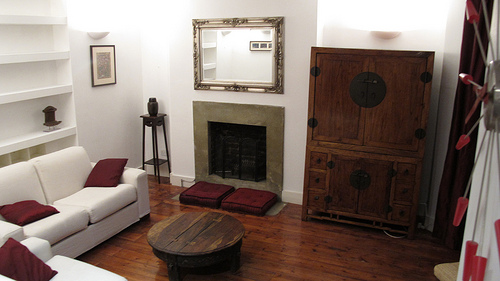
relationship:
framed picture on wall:
[89, 44, 117, 86] [125, 35, 167, 86]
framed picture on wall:
[84, 39, 129, 85] [125, 35, 167, 86]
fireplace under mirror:
[167, 102, 307, 207] [182, 7, 300, 102]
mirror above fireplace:
[191, 16, 285, 94] [190, 99, 288, 197]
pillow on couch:
[85, 155, 129, 186] [0, 142, 150, 258]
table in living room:
[146, 209, 248, 278] [0, 0, 500, 281]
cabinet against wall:
[298, 45, 435, 242] [135, 0, 466, 230]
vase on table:
[147, 97, 159, 117] [140, 112, 170, 182]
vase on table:
[142, 93, 167, 120] [134, 111, 180, 186]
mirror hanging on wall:
[193, 17, 285, 94] [138, 0, 318, 205]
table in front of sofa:
[146, 209, 248, 278] [0, 144, 154, 272]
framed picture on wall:
[89, 44, 117, 86] [68, 1, 144, 173]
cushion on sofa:
[53, 182, 139, 226] [13, 102, 193, 258]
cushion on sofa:
[22, 208, 90, 247] [13, 102, 193, 258]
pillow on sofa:
[85, 155, 129, 186] [0, 144, 154, 272]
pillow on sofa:
[0, 199, 59, 229] [0, 144, 154, 272]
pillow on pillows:
[2, 237, 59, 280] [15, 129, 200, 246]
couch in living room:
[4, 134, 152, 279] [4, 0, 491, 278]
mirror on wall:
[191, 16, 285, 94] [138, 0, 318, 205]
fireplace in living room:
[204, 118, 266, 189] [16, 16, 471, 278]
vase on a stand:
[147, 97, 159, 117] [141, 114, 178, 181]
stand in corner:
[139, 111, 172, 185] [129, 1, 154, 177]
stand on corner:
[139, 113, 172, 185] [134, 36, 173, 176]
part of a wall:
[113, 98, 128, 135] [3, 0, 469, 241]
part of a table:
[148, 120, 151, 125] [223, 213, 247, 250]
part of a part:
[209, 122, 221, 130] [226, 123, 243, 133]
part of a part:
[209, 122, 221, 130] [246, 126, 263, 141]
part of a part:
[209, 122, 221, 130] [214, 157, 232, 169]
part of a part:
[209, 122, 221, 130] [239, 167, 265, 179]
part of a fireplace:
[209, 122, 221, 130] [191, 99, 285, 207]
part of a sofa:
[78, 196, 113, 226] [0, 144, 154, 272]